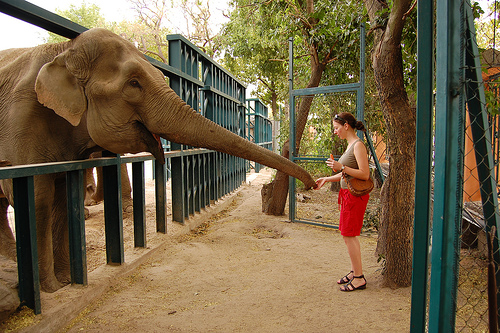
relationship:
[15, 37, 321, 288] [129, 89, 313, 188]
elephant has trunk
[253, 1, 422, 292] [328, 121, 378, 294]
trees behind woman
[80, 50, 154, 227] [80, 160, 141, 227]
elephant has legs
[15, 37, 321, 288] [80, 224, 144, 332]
elephant in dirt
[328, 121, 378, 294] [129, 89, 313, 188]
woman touching trunk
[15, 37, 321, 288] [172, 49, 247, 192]
elephant behind bars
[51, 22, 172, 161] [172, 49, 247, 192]
head sticking through bars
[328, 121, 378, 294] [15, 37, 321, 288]
woman feeds elephant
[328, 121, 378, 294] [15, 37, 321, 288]
woman near elephant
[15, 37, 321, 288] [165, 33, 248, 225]
elephant behind bars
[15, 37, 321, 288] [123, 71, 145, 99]
elephant has eye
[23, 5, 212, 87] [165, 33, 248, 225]
beam on bars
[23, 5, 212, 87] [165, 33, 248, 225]
beam on top of bars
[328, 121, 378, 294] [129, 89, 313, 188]
woman touches trunk